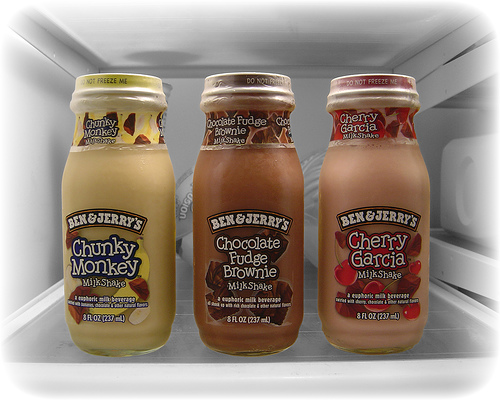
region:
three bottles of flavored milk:
[57, 64, 443, 354]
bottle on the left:
[61, 64, 176, 359]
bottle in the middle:
[188, 64, 305, 358]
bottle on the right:
[315, 68, 438, 355]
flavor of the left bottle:
[69, 233, 140, 283]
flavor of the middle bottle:
[216, 237, 283, 282]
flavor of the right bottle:
[345, 229, 409, 269]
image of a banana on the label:
[84, 230, 155, 326]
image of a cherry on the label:
[329, 240, 359, 285]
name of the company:
[203, 206, 294, 233]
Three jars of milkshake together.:
[59, 72, 432, 354]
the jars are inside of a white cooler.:
[7, 6, 490, 354]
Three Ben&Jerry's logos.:
[65, 208, 421, 230]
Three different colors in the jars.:
[63, 140, 433, 208]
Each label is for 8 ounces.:
[65, 310, 425, 326]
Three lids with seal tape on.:
[70, 73, 415, 109]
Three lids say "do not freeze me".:
[73, 73, 413, 95]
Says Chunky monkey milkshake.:
[67, 236, 147, 290]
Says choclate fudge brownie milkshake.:
[216, 232, 281, 292]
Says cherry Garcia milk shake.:
[349, 232, 408, 281]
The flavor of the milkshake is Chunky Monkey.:
[60, 71, 171, 353]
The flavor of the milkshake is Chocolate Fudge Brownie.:
[192, 72, 300, 352]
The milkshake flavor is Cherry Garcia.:
[318, 78, 428, 353]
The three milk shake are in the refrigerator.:
[63, 75, 429, 352]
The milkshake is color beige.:
[63, 74, 173, 353]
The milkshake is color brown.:
[194, 75, 304, 353]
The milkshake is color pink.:
[320, 74, 427, 351]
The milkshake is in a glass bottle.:
[62, 76, 175, 351]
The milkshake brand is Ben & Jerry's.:
[193, 78, 303, 355]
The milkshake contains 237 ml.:
[321, 75, 428, 354]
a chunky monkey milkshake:
[45, 53, 180, 367]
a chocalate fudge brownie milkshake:
[182, 67, 311, 360]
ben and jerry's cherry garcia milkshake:
[308, 100, 440, 373]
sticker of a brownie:
[252, 277, 294, 328]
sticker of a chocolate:
[67, 283, 89, 324]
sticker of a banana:
[83, 233, 154, 324]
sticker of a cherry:
[333, 243, 360, 283]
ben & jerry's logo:
[203, 205, 298, 231]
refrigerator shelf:
[1, 25, 491, 372]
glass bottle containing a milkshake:
[312, 67, 429, 362]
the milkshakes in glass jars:
[60, 71, 430, 352]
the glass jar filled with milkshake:
[60, 71, 175, 357]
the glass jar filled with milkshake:
[192, 70, 304, 354]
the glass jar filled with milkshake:
[318, 73, 429, 353]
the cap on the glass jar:
[72, 72, 164, 97]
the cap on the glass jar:
[201, 73, 293, 93]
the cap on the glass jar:
[325, 73, 419, 95]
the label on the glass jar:
[64, 206, 150, 324]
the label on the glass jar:
[206, 208, 292, 325]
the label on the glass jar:
[333, 206, 421, 320]